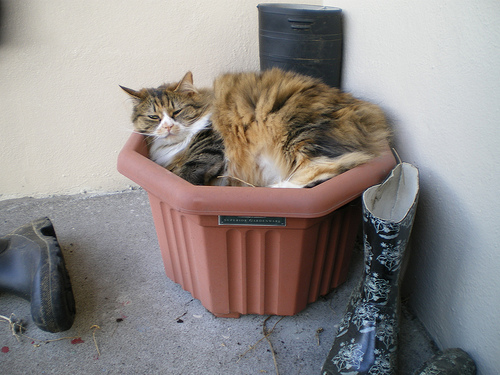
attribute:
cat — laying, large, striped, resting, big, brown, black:
[124, 74, 398, 194]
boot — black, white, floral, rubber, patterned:
[329, 164, 417, 374]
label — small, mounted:
[219, 214, 292, 228]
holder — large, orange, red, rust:
[122, 70, 396, 317]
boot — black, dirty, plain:
[6, 217, 75, 335]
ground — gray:
[4, 190, 497, 370]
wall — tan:
[3, 0, 499, 337]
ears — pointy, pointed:
[115, 71, 195, 99]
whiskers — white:
[132, 125, 202, 136]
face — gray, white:
[121, 101, 206, 146]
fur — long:
[223, 76, 371, 175]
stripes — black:
[145, 90, 178, 108]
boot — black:
[254, 2, 356, 87]